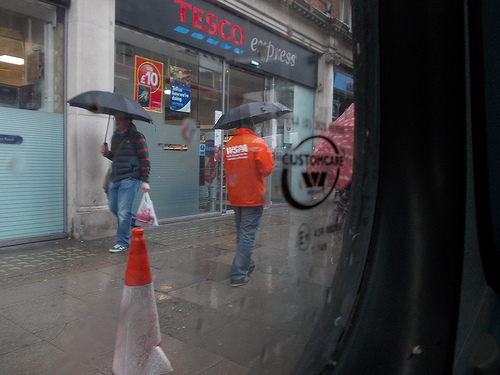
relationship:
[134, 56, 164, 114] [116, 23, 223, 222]
sign on window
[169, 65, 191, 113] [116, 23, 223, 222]
sign on window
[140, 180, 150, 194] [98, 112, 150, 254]
hand of person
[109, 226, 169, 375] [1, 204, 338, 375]
cone sitting on sidewalk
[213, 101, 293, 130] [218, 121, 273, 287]
umbrella over person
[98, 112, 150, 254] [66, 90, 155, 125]
person holding umbrella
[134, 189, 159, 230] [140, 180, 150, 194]
bag in hand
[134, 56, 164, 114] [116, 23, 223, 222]
sign inside window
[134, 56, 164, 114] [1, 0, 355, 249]
sign on building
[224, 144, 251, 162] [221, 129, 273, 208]
logo on jacket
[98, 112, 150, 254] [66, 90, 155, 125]
person walking with umbrella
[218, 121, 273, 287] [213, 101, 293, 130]
person walking with umbrella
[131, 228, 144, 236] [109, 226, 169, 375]
tip of cone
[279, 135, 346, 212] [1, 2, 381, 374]
sticker on window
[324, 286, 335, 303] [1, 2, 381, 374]
drop on window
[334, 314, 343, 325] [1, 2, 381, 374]
drop on window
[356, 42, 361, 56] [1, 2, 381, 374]
drop on window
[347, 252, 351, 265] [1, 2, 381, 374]
drop on window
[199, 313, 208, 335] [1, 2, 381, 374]
drop on window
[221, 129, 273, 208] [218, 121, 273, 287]
jacket worn by person